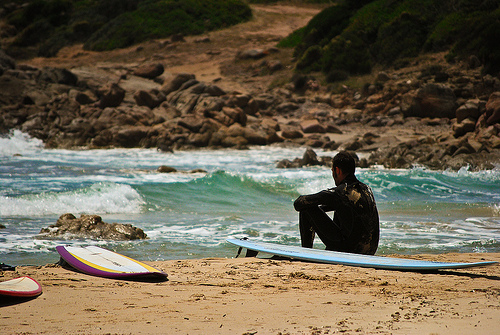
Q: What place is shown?
A: It is a shore.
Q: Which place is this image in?
A: It is at the shore.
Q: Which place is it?
A: It is a shore.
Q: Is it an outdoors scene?
A: Yes, it is outdoors.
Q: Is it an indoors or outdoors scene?
A: It is outdoors.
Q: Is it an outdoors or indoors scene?
A: It is outdoors.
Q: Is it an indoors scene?
A: No, it is outdoors.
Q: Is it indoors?
A: No, it is outdoors.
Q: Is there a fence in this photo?
A: No, there are no fences.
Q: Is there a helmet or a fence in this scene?
A: No, there are no fences or helmets.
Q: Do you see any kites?
A: No, there are no kites.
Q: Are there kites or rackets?
A: No, there are no kites or rackets.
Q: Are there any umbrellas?
A: No, there are no umbrellas.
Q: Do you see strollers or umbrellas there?
A: No, there are no umbrellas or strollers.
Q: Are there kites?
A: No, there are no kites.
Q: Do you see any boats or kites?
A: No, there are no kites or boats.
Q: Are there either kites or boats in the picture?
A: No, there are no kites or boats.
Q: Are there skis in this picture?
A: No, there are no skis.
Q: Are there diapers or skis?
A: No, there are no skis or diapers.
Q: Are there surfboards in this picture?
A: Yes, there is a surfboard.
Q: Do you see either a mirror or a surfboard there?
A: Yes, there is a surfboard.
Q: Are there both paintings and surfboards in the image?
A: No, there is a surfboard but no paintings.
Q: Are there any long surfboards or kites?
A: Yes, there is a long surfboard.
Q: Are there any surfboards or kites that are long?
A: Yes, the surfboard is long.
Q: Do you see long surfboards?
A: Yes, there is a long surfboard.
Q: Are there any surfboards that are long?
A: Yes, there is a surfboard that is long.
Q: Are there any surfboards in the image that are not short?
A: Yes, there is a long surfboard.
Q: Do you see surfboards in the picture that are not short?
A: Yes, there is a long surfboard.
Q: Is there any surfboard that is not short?
A: Yes, there is a long surfboard.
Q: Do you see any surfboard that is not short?
A: Yes, there is a long surfboard.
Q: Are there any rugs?
A: No, there are no rugs.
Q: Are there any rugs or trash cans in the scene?
A: No, there are no rugs or trash cans.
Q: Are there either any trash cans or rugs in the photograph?
A: No, there are no rugs or trash cans.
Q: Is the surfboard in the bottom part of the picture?
A: Yes, the surfboard is in the bottom of the image.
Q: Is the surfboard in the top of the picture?
A: No, the surfboard is in the bottom of the image.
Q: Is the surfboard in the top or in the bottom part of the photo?
A: The surfboard is in the bottom of the image.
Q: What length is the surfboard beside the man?
A: The surfboard is long.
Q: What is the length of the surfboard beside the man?
A: The surfboard is long.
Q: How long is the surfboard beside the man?
A: The surfboard is long.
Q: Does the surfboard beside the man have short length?
A: No, the surfboard is long.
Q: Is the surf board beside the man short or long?
A: The surfboard is long.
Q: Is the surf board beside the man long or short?
A: The surfboard is long.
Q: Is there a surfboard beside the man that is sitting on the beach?
A: Yes, there is a surfboard beside the man.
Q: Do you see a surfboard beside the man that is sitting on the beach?
A: Yes, there is a surfboard beside the man.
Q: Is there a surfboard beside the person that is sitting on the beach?
A: Yes, there is a surfboard beside the man.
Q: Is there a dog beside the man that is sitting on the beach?
A: No, there is a surfboard beside the man.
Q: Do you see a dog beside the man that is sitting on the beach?
A: No, there is a surfboard beside the man.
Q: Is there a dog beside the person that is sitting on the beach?
A: No, there is a surfboard beside the man.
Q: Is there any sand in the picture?
A: Yes, there is sand.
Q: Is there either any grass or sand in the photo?
A: Yes, there is sand.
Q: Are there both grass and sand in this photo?
A: No, there is sand but no grass.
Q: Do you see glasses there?
A: No, there are no glasses.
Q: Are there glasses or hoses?
A: No, there are no glasses or hoses.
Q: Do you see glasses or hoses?
A: No, there are no glasses or hoses.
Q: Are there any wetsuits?
A: Yes, there is a wetsuit.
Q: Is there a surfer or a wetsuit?
A: Yes, there is a wetsuit.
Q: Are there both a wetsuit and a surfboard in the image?
A: Yes, there are both a wetsuit and a surfboard.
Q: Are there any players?
A: No, there are no players.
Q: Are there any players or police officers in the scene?
A: No, there are no players or police officers.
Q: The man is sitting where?
A: The man is sitting on the beach.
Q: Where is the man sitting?
A: The man is sitting on the beach.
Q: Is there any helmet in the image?
A: No, there are no helmets.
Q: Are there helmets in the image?
A: No, there are no helmets.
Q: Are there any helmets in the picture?
A: No, there are no helmets.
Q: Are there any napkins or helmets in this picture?
A: No, there are no helmets or napkins.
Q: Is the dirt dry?
A: Yes, the dirt is dry.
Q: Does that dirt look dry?
A: Yes, the dirt is dry.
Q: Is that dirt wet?
A: No, the dirt is dry.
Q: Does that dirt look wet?
A: No, the dirt is dry.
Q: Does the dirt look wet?
A: No, the dirt is dry.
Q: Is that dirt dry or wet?
A: The dirt is dry.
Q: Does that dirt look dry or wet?
A: The dirt is dry.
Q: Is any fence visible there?
A: No, there are no fences.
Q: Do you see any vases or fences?
A: No, there are no fences or vases.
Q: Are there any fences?
A: No, there are no fences.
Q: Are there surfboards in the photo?
A: Yes, there is a surfboard.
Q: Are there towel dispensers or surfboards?
A: Yes, there is a surfboard.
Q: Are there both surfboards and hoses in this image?
A: No, there is a surfboard but no hoses.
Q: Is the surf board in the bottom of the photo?
A: Yes, the surf board is in the bottom of the image.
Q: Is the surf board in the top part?
A: No, the surf board is in the bottom of the image.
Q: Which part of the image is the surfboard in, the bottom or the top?
A: The surfboard is in the bottom of the image.